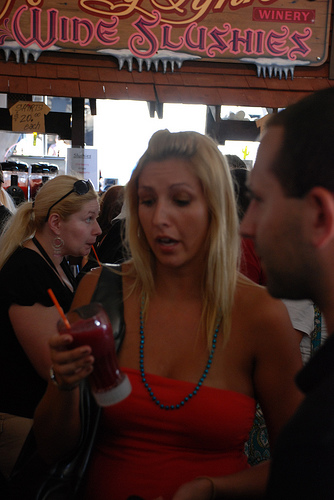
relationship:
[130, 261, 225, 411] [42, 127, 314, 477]
necklace on woman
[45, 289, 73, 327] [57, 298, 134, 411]
straw in a cup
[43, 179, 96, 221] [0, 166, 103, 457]
sunglasses on lady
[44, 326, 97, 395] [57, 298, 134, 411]
hand on cup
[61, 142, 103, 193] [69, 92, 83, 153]
paper on post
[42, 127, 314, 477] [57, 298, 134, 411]
woman holding cup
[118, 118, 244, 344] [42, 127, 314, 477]
hair on woman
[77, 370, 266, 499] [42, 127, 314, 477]
top on woman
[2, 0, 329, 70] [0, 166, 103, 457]
sign above lady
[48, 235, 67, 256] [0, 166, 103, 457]
earring on lady